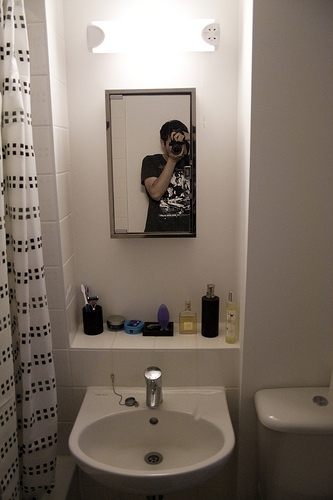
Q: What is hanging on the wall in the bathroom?
A: The mirror.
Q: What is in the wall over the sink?
A: The alcove.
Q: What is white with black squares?
A: The shower curtain.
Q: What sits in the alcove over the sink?
A: The grooming supplies.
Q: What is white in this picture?
A: The wall of the bathroom.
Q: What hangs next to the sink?
A: The shower curtain.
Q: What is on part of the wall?
A: White tile.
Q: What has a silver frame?
A: The mirror.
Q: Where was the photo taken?
A: In a bathroom.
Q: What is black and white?
A: The shower curtain.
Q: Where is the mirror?
A: On the wall.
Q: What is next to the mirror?
A: Shower curtain.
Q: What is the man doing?
A: Using a camera.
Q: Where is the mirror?
A: Above the sink.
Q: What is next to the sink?
A: Toilet.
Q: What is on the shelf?
A: Items.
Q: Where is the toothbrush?
A: In a cup.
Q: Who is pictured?
A: A man.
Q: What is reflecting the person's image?
A: Mirror.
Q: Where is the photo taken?
A: Bathroom.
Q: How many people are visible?
A: One.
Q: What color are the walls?
A: White.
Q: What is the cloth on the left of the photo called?
A: Shower curtain.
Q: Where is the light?
A: Above the mirror.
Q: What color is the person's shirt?
A: Black.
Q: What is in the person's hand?
A: Camera.